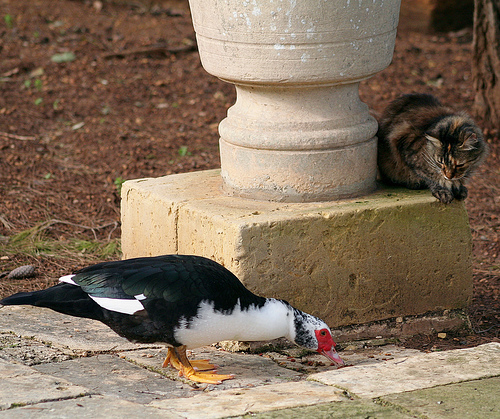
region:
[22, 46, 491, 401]
a cat looking at a duck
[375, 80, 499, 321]
cat sitting on a concrete block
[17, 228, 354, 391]
black and white duck looking for food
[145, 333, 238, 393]
orange duck feet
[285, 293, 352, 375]
duck's head and beak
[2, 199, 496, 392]
a duck next to a concrete block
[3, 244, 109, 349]
duck tail in black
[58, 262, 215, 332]
black and white duck wings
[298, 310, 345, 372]
duck's right eye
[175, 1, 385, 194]
part of a concrete plant pot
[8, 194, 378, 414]
bird standing on ground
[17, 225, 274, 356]
black feather of bird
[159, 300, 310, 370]
white feathers on bird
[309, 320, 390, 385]
red feathers on bird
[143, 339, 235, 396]
orange feet on bird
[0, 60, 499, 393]
cat looking at bird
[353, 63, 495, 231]
cat is dark brown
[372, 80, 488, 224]
cat has dark stripes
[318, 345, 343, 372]
red beak on bird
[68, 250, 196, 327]
dark green feathers on bird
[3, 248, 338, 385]
black, white red and yellow duck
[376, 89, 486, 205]
black, gray and brown cat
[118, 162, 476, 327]
light gray cement pedestal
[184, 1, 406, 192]
tan cement round object on a pedestal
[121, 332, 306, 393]
grya cement rectangle paver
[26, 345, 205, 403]
dark gray rectangle paver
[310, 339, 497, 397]
light gray recangular paver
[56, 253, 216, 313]
black and white wing of a duck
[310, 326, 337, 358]
red marking around the eye of a duck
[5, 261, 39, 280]
pine cone laying on the ground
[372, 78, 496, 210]
the cat is watching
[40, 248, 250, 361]
duck's feathers are black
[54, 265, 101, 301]
Tail of eating bird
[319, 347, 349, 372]
beak of hungry bird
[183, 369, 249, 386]
Foot of hungry bird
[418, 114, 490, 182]
Cat watching hungry bird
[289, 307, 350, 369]
Head of hungry bird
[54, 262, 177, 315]
Wing of hungry bird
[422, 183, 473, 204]
Paws of watching cat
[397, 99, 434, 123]
Back of watching cat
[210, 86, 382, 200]
Base of decorative urn next to cat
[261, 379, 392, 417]
Stone blocks near bird